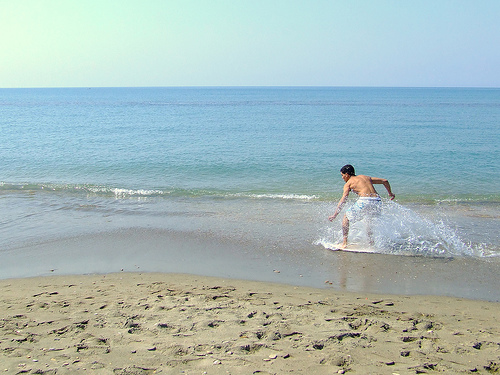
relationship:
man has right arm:
[325, 160, 405, 256] [368, 174, 400, 201]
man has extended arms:
[325, 160, 405, 256] [332, 187, 351, 218]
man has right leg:
[325, 160, 405, 256] [366, 216, 385, 255]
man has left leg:
[325, 160, 405, 256] [335, 207, 367, 253]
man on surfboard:
[325, 160, 405, 256] [332, 244, 406, 258]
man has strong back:
[325, 160, 405, 256] [346, 174, 384, 200]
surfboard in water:
[332, 244, 406, 258] [268, 190, 499, 264]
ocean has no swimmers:
[14, 87, 486, 161] [48, 110, 467, 160]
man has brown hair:
[325, 160, 405, 256] [340, 164, 355, 177]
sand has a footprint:
[32, 314, 92, 349] [51, 322, 86, 342]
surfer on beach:
[325, 160, 405, 256] [13, 272, 498, 375]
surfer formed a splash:
[325, 160, 405, 256] [315, 197, 498, 261]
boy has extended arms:
[325, 160, 405, 256] [327, 177, 398, 224]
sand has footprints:
[32, 314, 92, 349] [21, 290, 418, 349]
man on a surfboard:
[325, 160, 405, 256] [332, 244, 406, 258]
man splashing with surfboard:
[325, 160, 405, 256] [332, 244, 406, 258]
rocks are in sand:
[260, 350, 298, 369] [101, 293, 408, 372]